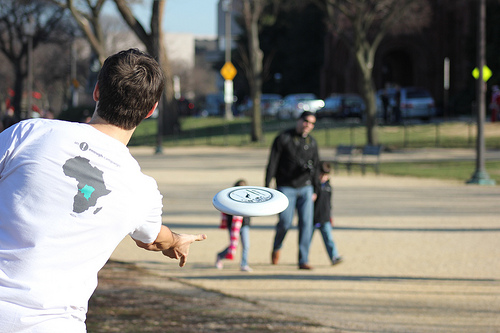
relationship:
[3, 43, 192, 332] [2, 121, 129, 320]
man has shirt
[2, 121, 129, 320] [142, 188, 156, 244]
shirt has sleeve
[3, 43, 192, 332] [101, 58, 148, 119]
man has hair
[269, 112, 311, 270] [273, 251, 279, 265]
man has shoe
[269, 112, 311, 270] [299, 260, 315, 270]
man has shoe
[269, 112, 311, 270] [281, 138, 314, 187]
man has jacket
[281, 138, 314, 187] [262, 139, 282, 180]
jacket has sleeve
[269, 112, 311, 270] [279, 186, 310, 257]
man has pants